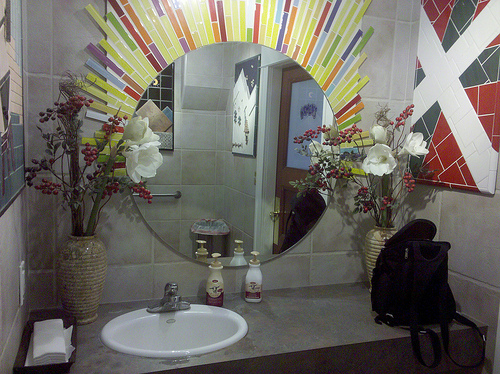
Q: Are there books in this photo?
A: No, there are no books.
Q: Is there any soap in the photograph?
A: Yes, there is a soap.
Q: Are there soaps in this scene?
A: Yes, there is a soap.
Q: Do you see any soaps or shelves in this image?
A: Yes, there is a soap.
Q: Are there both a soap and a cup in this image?
A: No, there is a soap but no cups.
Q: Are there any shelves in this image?
A: No, there are no shelves.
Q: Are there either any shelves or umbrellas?
A: No, there are no shelves or umbrellas.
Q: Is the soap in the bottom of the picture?
A: Yes, the soap is in the bottom of the image.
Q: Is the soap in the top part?
A: No, the soap is in the bottom of the image.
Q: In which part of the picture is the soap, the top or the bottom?
A: The soap is in the bottom of the image.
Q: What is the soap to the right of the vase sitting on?
A: The soap is sitting on the counter top.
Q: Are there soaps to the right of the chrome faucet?
A: Yes, there is a soap to the right of the faucet.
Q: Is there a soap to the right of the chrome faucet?
A: Yes, there is a soap to the right of the faucet.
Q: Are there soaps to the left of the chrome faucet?
A: No, the soap is to the right of the faucet.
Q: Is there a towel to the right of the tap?
A: No, there is a soap to the right of the tap.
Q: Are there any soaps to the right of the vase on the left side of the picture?
A: Yes, there is a soap to the right of the vase.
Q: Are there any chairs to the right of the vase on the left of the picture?
A: No, there is a soap to the right of the vase.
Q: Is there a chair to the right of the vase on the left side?
A: No, there is a soap to the right of the vase.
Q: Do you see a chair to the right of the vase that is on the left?
A: No, there is a soap to the right of the vase.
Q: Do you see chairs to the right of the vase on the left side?
A: No, there is a soap to the right of the vase.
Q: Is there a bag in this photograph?
A: Yes, there is a bag.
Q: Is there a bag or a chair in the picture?
A: Yes, there is a bag.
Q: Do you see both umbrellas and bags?
A: No, there is a bag but no umbrellas.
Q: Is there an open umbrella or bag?
A: Yes, there is an open bag.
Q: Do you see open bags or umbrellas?
A: Yes, there is an open bag.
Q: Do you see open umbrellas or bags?
A: Yes, there is an open bag.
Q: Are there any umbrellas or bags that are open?
A: Yes, the bag is open.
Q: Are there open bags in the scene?
A: Yes, there is an open bag.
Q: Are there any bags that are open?
A: Yes, there is a bag that is open.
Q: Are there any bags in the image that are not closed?
A: Yes, there is a open bag.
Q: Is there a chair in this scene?
A: No, there are no chairs.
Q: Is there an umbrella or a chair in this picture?
A: No, there are no chairs or umbrellas.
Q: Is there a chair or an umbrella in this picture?
A: No, there are no chairs or umbrellas.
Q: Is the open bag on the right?
A: Yes, the bag is on the right of the image.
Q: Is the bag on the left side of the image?
A: No, the bag is on the right of the image.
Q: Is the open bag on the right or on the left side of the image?
A: The bag is on the right of the image.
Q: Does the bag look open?
A: Yes, the bag is open.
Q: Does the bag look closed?
A: No, the bag is open.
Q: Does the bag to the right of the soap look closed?
A: No, the bag is open.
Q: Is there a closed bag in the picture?
A: No, there is a bag but it is open.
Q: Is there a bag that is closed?
A: No, there is a bag but it is open.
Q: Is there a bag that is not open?
A: No, there is a bag but it is open.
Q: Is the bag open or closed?
A: The bag is open.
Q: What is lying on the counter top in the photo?
A: The bag is lying on the counter top.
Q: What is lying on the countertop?
A: The bag is lying on the counter top.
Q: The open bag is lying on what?
A: The bag is lying on the counter top.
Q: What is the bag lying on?
A: The bag is lying on the counter top.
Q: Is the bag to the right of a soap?
A: Yes, the bag is to the right of a soap.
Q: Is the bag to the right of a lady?
A: No, the bag is to the right of a soap.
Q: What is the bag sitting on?
A: The bag is sitting on the countertop.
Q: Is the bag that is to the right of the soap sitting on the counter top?
A: Yes, the bag is sitting on the counter top.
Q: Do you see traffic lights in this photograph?
A: No, there are no traffic lights.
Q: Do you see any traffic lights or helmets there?
A: No, there are no traffic lights or helmets.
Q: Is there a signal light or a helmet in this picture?
A: No, there are no traffic lights or helmets.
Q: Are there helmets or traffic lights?
A: No, there are no traffic lights or helmets.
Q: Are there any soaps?
A: Yes, there is a soap.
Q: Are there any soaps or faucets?
A: Yes, there is a soap.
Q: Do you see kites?
A: No, there are no kites.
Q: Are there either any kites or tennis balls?
A: No, there are no kites or tennis balls.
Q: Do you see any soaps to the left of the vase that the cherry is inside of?
A: Yes, there is a soap to the left of the vase.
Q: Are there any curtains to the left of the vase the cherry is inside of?
A: No, there is a soap to the left of the vase.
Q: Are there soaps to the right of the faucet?
A: Yes, there is a soap to the right of the faucet.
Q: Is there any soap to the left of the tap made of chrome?
A: No, the soap is to the right of the tap.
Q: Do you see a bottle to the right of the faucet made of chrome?
A: No, there is a soap to the right of the tap.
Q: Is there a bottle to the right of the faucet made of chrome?
A: No, there is a soap to the right of the tap.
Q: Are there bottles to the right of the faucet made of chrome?
A: No, there is a soap to the right of the tap.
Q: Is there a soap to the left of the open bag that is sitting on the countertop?
A: Yes, there is a soap to the left of the bag.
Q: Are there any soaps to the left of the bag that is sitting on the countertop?
A: Yes, there is a soap to the left of the bag.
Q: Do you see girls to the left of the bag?
A: No, there is a soap to the left of the bag.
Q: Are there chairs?
A: No, there are no chairs.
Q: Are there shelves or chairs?
A: No, there are no chairs or shelves.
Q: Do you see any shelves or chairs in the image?
A: No, there are no chairs or shelves.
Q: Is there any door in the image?
A: Yes, there is a door.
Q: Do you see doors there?
A: Yes, there is a door.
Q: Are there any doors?
A: Yes, there is a door.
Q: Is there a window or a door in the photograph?
A: Yes, there is a door.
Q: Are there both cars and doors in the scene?
A: No, there is a door but no cars.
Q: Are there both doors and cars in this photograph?
A: No, there is a door but no cars.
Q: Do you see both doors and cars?
A: No, there is a door but no cars.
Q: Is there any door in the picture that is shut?
A: Yes, there is a shut door.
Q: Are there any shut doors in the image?
A: Yes, there is a shut door.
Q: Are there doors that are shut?
A: Yes, there is a door that is shut.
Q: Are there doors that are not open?
A: Yes, there is an shut door.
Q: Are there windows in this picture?
A: No, there are no windows.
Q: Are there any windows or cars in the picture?
A: No, there are no windows or cars.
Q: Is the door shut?
A: Yes, the door is shut.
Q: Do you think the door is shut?
A: Yes, the door is shut.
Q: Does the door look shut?
A: Yes, the door is shut.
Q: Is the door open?
A: No, the door is shut.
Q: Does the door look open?
A: No, the door is shut.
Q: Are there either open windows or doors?
A: No, there is a door but it is shut.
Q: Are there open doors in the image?
A: No, there is a door but it is shut.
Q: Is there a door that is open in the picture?
A: No, there is a door but it is shut.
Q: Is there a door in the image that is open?
A: No, there is a door but it is shut.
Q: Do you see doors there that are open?
A: No, there is a door but it is shut.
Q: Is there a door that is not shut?
A: No, there is a door but it is shut.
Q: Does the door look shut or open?
A: The door is shut.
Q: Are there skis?
A: No, there are no skis.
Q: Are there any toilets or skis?
A: No, there are no skis or toilets.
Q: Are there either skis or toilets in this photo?
A: No, there are no skis or toilets.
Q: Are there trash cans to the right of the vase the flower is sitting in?
A: Yes, there is a trash can to the right of the vase.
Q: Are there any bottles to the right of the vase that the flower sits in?
A: No, there is a trash can to the right of the vase.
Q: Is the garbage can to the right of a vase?
A: Yes, the garbage can is to the right of a vase.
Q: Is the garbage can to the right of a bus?
A: No, the garbage can is to the right of a vase.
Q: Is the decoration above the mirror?
A: Yes, the decoration is above the mirror.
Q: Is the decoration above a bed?
A: No, the decoration is above the mirror.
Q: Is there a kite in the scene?
A: No, there are no kites.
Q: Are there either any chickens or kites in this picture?
A: No, there are no kites or chickens.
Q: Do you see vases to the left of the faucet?
A: Yes, there is a vase to the left of the faucet.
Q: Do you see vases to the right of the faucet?
A: No, the vase is to the left of the faucet.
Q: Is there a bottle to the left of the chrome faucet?
A: No, there is a vase to the left of the tap.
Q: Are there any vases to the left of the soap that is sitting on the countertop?
A: Yes, there is a vase to the left of the soap.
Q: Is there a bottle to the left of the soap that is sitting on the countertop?
A: No, there is a vase to the left of the soap.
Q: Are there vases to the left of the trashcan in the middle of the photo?
A: Yes, there is a vase to the left of the garbage bin.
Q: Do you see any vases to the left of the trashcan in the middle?
A: Yes, there is a vase to the left of the garbage bin.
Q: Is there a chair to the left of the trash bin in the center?
A: No, there is a vase to the left of the garbage can.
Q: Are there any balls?
A: No, there are no balls.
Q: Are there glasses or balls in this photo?
A: No, there are no balls or glasses.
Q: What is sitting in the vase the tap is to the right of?
A: The flower is sitting in the vase.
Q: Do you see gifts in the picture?
A: No, there are no gifts.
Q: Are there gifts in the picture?
A: No, there are no gifts.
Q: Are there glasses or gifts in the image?
A: No, there are no gifts or glasses.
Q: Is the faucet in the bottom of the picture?
A: Yes, the faucet is in the bottom of the image.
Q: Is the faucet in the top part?
A: No, the faucet is in the bottom of the image.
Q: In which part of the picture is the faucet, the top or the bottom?
A: The faucet is in the bottom of the image.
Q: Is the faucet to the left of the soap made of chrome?
A: Yes, the tap is made of chrome.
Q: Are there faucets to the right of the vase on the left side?
A: Yes, there is a faucet to the right of the vase.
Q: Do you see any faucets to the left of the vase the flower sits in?
A: No, the faucet is to the right of the vase.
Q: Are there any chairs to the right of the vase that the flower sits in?
A: No, there is a faucet to the right of the vase.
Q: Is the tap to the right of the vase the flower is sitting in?
A: Yes, the tap is to the right of the vase.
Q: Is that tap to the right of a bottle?
A: No, the tap is to the right of the vase.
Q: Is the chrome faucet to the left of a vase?
A: No, the faucet is to the right of a vase.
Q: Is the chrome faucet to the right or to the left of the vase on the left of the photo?
A: The faucet is to the right of the vase.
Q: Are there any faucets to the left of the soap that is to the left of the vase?
A: Yes, there is a faucet to the left of the soap.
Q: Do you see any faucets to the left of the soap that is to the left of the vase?
A: Yes, there is a faucet to the left of the soap.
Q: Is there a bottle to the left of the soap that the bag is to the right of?
A: No, there is a faucet to the left of the soap.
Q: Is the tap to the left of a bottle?
A: No, the tap is to the left of a soap.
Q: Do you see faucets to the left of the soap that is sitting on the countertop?
A: Yes, there is a faucet to the left of the soap.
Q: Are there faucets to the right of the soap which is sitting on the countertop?
A: No, the faucet is to the left of the soap.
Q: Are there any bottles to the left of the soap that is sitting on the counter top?
A: No, there is a faucet to the left of the soap.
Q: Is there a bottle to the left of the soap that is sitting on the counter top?
A: No, there is a faucet to the left of the soap.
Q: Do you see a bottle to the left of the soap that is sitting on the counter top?
A: No, there is a faucet to the left of the soap.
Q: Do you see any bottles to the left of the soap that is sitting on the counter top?
A: No, there is a faucet to the left of the soap.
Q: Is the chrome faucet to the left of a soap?
A: Yes, the tap is to the left of a soap.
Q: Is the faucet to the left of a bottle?
A: No, the faucet is to the left of a soap.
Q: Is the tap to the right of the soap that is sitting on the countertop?
A: No, the tap is to the left of the soap.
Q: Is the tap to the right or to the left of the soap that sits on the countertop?
A: The tap is to the left of the soap.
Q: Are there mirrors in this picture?
A: Yes, there is a mirror.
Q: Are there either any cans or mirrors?
A: Yes, there is a mirror.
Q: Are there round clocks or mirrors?
A: Yes, there is a round mirror.